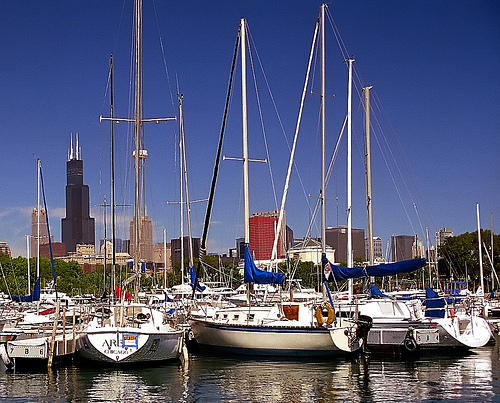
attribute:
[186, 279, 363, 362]
boat — white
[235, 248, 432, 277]
cover — blue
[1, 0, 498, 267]
sky — blue and clear, blue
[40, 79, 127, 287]
building — red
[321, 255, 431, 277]
sail — blue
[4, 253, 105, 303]
leaves — green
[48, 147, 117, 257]
building — tall and black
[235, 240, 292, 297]
flag — blue 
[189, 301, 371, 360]
sailboat — white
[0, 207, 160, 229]
cloud — smal and white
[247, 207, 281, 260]
building — red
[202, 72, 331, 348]
mast — white